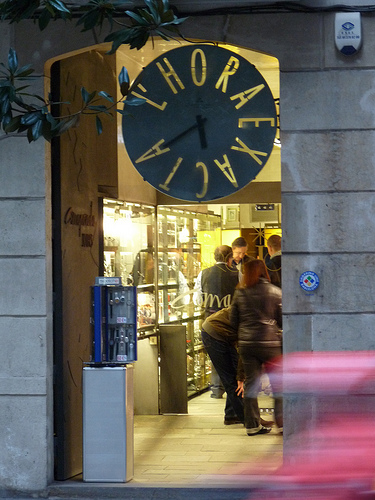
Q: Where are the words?
A: On the clock.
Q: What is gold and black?
A: The clock.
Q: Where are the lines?
A: On the building.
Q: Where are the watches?
A: In a display.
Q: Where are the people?
A: Inside the store.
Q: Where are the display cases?
A: In the store.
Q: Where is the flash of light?
A: Outside the store.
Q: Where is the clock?
A: On a building.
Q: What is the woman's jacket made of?
A: Leather.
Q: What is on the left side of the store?
A: Display case.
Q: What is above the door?
A: Clock.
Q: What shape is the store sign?
A: Round.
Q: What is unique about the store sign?
A: It's a clock.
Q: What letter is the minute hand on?
A: A.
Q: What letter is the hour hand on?
A: C.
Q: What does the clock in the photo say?
A: L'Horaexacta.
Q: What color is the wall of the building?
A: Gray.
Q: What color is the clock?
A: Black.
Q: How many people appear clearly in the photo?
A: Five.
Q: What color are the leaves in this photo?
A: Green.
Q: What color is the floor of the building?
A: White.